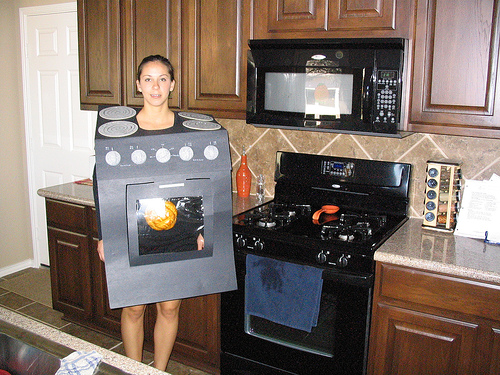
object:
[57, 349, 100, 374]
rag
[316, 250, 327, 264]
handle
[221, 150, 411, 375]
oven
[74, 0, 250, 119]
cabinets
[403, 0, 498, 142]
cabinets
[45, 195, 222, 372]
cabinets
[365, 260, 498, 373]
cabinets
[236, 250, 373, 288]
rack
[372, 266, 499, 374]
brown cabinet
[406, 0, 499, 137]
brown cabinet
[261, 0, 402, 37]
brown cabinet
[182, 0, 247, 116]
brown cabinet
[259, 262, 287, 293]
stain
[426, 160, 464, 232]
sailboats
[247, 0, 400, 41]
cabinets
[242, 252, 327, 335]
towel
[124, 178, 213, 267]
door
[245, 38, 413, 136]
microwave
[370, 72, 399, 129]
control panel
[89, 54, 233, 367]
woman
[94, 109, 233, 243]
costume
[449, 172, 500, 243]
papers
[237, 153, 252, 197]
bottle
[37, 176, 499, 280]
counter-top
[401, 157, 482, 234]
rack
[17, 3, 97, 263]
door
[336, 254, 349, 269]
handle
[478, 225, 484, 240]
holder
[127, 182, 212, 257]
panel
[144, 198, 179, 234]
bun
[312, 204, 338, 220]
spoon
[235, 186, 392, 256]
range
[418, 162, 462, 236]
spicerack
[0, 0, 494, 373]
wall